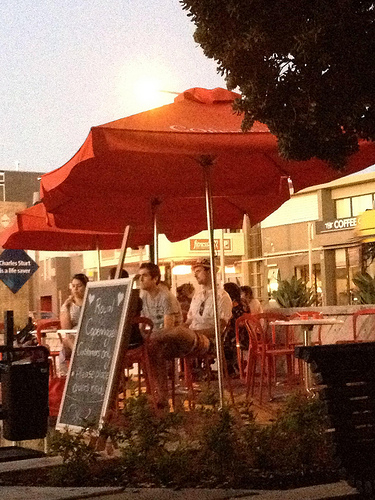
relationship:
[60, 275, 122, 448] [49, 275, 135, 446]
menu on chalkboard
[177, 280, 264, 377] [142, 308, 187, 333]
women have dinner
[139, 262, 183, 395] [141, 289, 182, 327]
friend wearing t-shirt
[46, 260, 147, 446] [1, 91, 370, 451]
chalkboard at restaurant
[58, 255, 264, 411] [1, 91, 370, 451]
patrons at restaurant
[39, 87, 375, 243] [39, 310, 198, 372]
canopy covering restaurant table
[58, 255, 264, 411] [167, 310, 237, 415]
patrons sitting in chairs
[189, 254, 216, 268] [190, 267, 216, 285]
hat on head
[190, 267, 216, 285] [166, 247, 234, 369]
head of man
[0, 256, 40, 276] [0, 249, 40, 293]
writing on sign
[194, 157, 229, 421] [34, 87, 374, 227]
stand for umbrella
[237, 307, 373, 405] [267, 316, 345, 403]
chairs around table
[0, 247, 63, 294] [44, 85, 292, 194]
sign hanging from canopy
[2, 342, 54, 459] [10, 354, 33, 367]
garbage can with trash